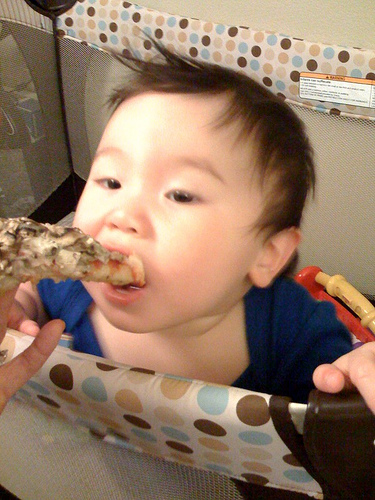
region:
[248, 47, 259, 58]
polka dot on baby decoration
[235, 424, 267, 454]
polka dot on baby decoration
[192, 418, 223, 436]
polka dot on baby decoration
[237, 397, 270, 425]
polka dot on baby decoration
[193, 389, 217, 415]
polka dot on baby decoration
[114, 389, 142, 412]
polka dot on baby decoration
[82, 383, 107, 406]
polka dot on baby decoration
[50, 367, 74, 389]
polka dot on baby decoration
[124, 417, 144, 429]
polka dot on baby decoration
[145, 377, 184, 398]
polka dot on baby decoration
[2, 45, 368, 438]
Small baby eating.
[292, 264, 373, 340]
Toy in the background.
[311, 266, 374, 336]
Yellow handled toy in the background.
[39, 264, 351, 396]
Blue tshirt on the child.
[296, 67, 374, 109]
Warnings posted on the playpen.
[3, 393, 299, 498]
Mesh front on the playpen.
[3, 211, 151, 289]
Pizza being eaten by child.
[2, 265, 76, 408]
Another person feeding the child.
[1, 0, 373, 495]
Polka dot pattern on playpen.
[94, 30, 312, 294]
Child's hair sticking up.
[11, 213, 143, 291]
the pizza is in the mouth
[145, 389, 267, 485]
the chiar is dotted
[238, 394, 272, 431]
the spot is brwon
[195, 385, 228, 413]
the spot is green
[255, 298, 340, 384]
the shirt is blue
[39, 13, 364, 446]
the baby is in the crib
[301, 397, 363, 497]
the corner is brown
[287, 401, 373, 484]
the corner is plastic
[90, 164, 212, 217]
the eyes are open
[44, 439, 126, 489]
the net has holes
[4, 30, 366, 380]
a baby with black hair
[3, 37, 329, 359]
a baby is eating a pizza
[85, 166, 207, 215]
black eyes of a baby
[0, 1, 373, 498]
baby stands in a crib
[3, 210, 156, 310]
a piece of pizza in a mouth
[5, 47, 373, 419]
baby wears a blue top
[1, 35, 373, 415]
baby hands are over the crib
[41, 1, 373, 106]
border of crib has brown and blue dots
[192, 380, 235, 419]
a blue dot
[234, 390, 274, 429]
a dark brown dot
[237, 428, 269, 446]
polka dot on baby bedding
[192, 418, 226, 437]
polka dot on baby bedding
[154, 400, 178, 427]
polka dot on baby bedding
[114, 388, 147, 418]
polka dot on baby bedding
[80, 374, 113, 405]
polka dot on baby bedding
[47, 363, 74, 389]
polka dot on baby bedding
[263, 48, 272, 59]
polka dot on baby bedding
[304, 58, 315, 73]
polka dot on baby bedding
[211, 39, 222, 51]
polka dot on baby bedding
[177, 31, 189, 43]
polka dot on baby bedding